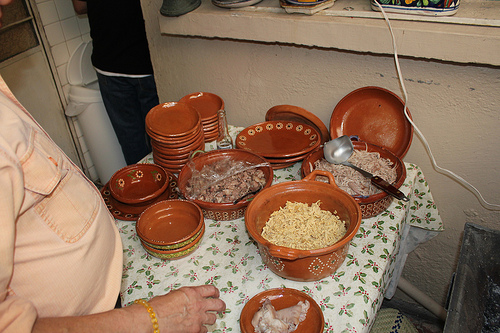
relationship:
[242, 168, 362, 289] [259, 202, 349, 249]
bowl of food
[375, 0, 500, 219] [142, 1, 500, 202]
cord down wall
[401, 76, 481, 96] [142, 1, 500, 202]
marks on wall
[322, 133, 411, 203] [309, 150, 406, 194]
ladle on food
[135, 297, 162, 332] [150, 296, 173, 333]
band around wrist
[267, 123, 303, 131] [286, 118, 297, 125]
design around edge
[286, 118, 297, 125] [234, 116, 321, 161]
edge of plate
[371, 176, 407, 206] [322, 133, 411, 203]
handle of ladle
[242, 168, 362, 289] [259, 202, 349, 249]
bowl of rice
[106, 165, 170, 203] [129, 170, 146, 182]
bowl with print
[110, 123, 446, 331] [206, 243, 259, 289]
tablecloth with print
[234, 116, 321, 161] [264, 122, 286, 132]
plate with print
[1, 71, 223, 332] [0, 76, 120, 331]
person wearing shirt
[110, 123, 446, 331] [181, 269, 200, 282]
tablecloth has missel toe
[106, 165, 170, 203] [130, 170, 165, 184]
bowl has sunflowers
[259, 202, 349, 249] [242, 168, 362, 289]
noodles in pot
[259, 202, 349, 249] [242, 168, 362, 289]
rice in pot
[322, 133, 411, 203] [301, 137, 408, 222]
ladle on bowl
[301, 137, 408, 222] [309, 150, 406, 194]
bowl of food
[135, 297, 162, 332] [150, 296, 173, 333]
bracelet on wrist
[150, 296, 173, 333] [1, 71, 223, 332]
wrist of person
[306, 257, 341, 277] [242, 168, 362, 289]
design on pot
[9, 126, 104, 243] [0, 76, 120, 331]
pocket on shirt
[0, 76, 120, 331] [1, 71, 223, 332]
shirt of man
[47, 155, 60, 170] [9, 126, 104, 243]
hole on pocket